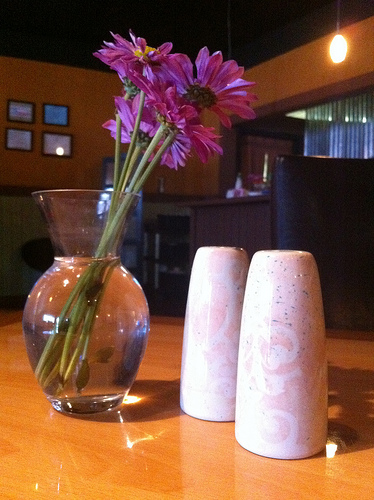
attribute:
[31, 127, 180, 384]
stem — green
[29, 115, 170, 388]
stem — green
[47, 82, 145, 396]
stem — green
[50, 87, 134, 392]
stem — green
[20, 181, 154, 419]
vase — clear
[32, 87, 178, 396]
stems — green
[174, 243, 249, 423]
shaker — white, salt shaker, pepper shaker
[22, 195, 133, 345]
vase — glass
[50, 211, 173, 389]
vase — glass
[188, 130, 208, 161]
petals — pink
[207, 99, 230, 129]
petals — pink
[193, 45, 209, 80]
petals — pink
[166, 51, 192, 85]
petals — pink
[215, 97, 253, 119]
petals — pink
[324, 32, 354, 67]
light — on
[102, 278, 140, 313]
water — clear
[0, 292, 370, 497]
table — tan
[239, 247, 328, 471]
shaker — white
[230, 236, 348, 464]
shaker — spotted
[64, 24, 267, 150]
flowers — purple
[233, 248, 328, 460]
shaker — salt shaker, pepper shaker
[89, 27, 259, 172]
flowers — pink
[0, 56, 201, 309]
wall — orange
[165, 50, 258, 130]
flower — purple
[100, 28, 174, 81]
flower — purple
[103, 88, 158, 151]
flower — purple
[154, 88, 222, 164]
flower — purple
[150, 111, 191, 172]
flower — purple